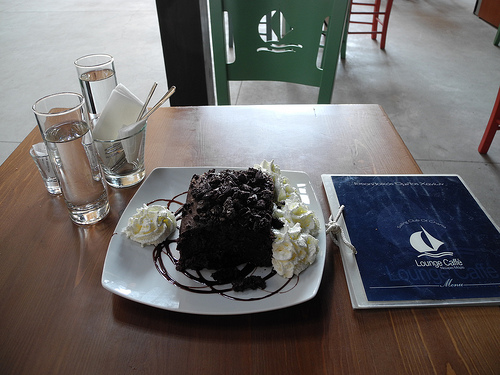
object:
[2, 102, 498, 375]
table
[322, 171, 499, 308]
menu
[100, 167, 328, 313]
plate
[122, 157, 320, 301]
sauce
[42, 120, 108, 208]
water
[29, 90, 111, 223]
glass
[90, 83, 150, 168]
napkin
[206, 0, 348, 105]
chair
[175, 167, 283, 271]
cake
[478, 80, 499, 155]
leg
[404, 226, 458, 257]
logo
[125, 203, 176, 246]
cream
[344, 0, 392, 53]
chair